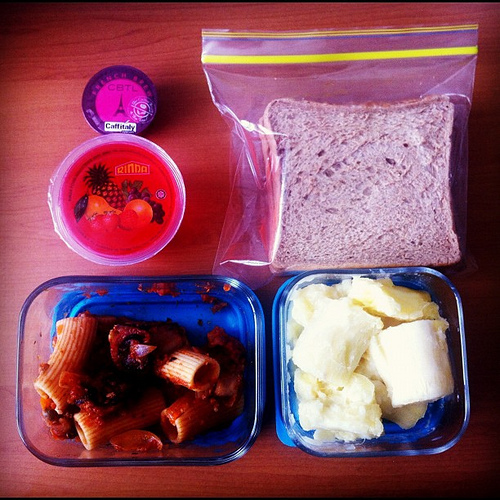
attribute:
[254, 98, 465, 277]
bag — plastic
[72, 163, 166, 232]
fruit — pictured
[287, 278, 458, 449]
potatoes — mashed, buttered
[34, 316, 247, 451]
pasta — cooked, meaty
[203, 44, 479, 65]
seal — yellow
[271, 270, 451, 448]
bowl — blue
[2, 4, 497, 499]
table — smooth, wooden, wood, brown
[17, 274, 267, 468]
container — square, for storage, glass, open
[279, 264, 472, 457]
container — small, clear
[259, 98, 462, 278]
sandwich — here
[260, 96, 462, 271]
bread — wheat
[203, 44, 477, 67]
stripe — yellow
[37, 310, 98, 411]
ziti — baked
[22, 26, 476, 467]
lunch — packed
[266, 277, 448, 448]
lid — blue